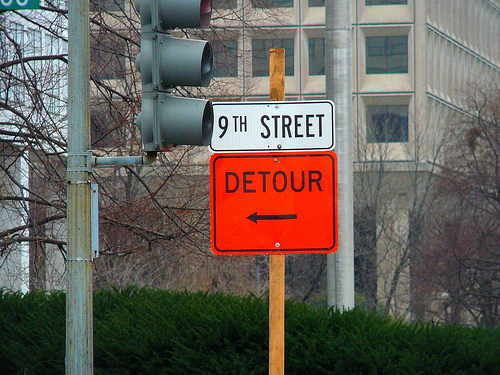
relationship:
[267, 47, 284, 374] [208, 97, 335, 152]
pole on sign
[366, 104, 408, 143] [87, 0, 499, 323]
window on building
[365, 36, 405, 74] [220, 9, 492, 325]
reflection on building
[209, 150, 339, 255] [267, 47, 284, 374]
detour sign on a pole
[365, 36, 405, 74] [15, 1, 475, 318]
reflection of a building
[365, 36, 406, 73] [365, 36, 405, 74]
reflection coming off from reflection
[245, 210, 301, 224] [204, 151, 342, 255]
arrow on sign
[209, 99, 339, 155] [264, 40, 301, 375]
sign attached to a pole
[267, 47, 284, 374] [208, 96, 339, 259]
pole holding sign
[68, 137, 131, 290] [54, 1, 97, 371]
light on a pole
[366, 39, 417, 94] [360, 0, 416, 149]
building with windows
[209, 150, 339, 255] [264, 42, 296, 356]
detour sign on pole